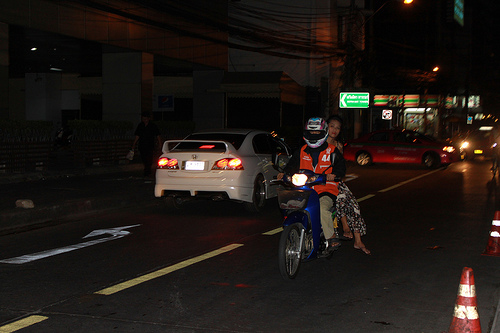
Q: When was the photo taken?
A: Night.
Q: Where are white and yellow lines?
A: On the road.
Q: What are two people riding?
A: A motorbike.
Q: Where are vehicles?
A: On the road.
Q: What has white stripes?
A: Orange cones.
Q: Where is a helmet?
A: On rider's head.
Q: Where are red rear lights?
A: On back of white car.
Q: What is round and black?
A: Tires.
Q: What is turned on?
A: Car's headlights.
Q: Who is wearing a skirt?
A: Woman on motorbike.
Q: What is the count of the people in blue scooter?
A: Two.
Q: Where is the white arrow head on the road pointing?
A: To the left.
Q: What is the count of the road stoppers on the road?
A: Two.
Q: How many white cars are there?
A: One.